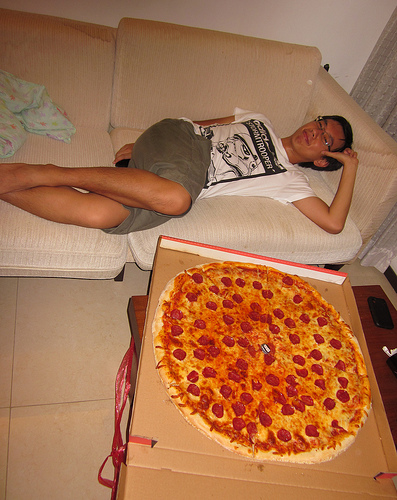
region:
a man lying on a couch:
[4, 10, 396, 274]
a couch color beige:
[1, 3, 395, 278]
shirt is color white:
[182, 102, 313, 216]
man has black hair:
[259, 91, 363, 202]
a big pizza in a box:
[108, 229, 391, 494]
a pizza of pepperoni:
[148, 254, 372, 468]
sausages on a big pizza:
[154, 254, 375, 471]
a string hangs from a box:
[88, 325, 157, 494]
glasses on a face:
[313, 110, 334, 149]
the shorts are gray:
[102, 106, 216, 236]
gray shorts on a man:
[106, 116, 213, 244]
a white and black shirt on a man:
[175, 104, 317, 199]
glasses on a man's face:
[312, 114, 335, 156]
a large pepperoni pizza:
[152, 259, 371, 468]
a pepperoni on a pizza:
[170, 344, 188, 361]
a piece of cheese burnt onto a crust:
[152, 344, 166, 351]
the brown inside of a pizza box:
[117, 247, 396, 498]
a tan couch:
[0, 7, 395, 285]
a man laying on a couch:
[0, 104, 360, 244]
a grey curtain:
[348, 6, 395, 144]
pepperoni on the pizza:
[283, 333, 298, 346]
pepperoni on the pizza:
[280, 405, 293, 417]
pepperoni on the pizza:
[301, 425, 318, 435]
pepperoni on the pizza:
[231, 402, 246, 414]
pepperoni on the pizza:
[260, 354, 273, 364]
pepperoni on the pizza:
[201, 367, 215, 380]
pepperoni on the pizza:
[222, 334, 241, 351]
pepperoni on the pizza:
[207, 344, 217, 358]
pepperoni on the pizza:
[304, 421, 317, 441]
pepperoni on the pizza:
[306, 344, 317, 359]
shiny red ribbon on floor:
[103, 421, 127, 453]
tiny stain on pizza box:
[237, 461, 269, 472]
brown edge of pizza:
[299, 452, 320, 462]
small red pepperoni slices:
[247, 409, 279, 435]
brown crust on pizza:
[165, 355, 176, 372]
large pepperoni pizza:
[158, 252, 388, 482]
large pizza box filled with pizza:
[133, 242, 388, 498]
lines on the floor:
[6, 373, 60, 437]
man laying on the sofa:
[101, 109, 386, 198]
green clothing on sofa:
[15, 69, 94, 140]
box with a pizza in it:
[123, 233, 396, 498]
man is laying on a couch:
[3, 112, 359, 233]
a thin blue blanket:
[1, 69, 73, 159]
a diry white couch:
[2, 5, 395, 286]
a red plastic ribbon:
[94, 337, 136, 498]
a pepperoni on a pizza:
[169, 324, 183, 335]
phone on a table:
[364, 293, 392, 329]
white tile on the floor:
[1, 270, 147, 498]